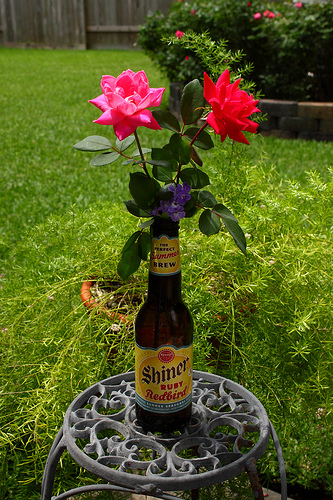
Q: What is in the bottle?
A: Flowers.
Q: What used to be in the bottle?
A: Shiner Ruby Redbird beer.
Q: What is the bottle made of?
A: Glass.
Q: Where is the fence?
A: The perimeter of the yard.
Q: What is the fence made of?
A: Wood.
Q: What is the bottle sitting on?
A: A stand.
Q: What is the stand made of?
A: Metal.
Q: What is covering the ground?
A: Grass.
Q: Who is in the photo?
A: No people.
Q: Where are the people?
A: None in photo.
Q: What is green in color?
A: Grass.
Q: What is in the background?
A: A fence.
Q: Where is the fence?
A: In the distance.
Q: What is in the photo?
A: Bottle with flowers.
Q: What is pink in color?
A: Flowers.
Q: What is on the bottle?
A: Writing.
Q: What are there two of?
A: Flowers.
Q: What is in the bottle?
A: Flowers.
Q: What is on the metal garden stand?
A: A bottle with flowers.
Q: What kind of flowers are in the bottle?
A: Roses.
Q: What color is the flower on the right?
A: Red.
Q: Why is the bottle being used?
A: As a vase.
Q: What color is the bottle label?
A: Yellow.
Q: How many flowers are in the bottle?
A: 3.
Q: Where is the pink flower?
A: On the left.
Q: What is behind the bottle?
A: Flower pot.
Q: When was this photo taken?
A: Daytime.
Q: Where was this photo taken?
A: In a backyard.